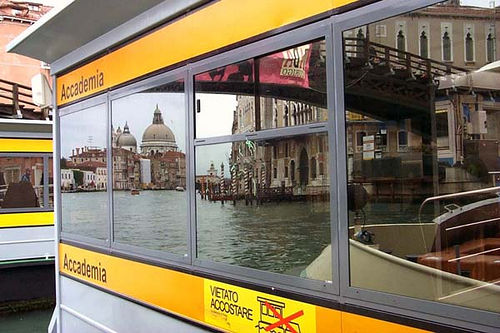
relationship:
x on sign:
[264, 299, 307, 333] [203, 278, 317, 332]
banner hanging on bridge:
[178, 41, 310, 87] [310, 37, 499, 137]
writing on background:
[59, 69, 107, 102] [57, 0, 354, 108]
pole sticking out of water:
[220, 163, 228, 208] [62, 192, 499, 279]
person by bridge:
[35, 59, 57, 122] [310, 37, 499, 137]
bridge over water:
[310, 37, 499, 137] [62, 192, 499, 279]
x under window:
[264, 299, 307, 333] [57, 0, 499, 331]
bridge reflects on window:
[310, 37, 499, 137] [57, 0, 499, 331]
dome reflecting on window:
[141, 103, 178, 145] [57, 0, 499, 331]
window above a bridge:
[57, 0, 499, 331] [310, 37, 499, 137]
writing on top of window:
[59, 69, 107, 102] [57, 0, 499, 331]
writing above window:
[59, 69, 107, 102] [57, 0, 499, 331]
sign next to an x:
[203, 278, 317, 332] [264, 299, 307, 333]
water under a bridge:
[62, 192, 499, 279] [310, 37, 499, 137]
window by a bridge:
[57, 0, 499, 331] [310, 37, 499, 137]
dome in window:
[141, 103, 178, 145] [57, 0, 499, 331]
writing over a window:
[59, 69, 107, 102] [57, 0, 499, 331]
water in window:
[62, 192, 499, 279] [57, 0, 499, 331]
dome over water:
[141, 103, 178, 145] [62, 192, 499, 279]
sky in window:
[62, 92, 237, 178] [57, 0, 499, 331]